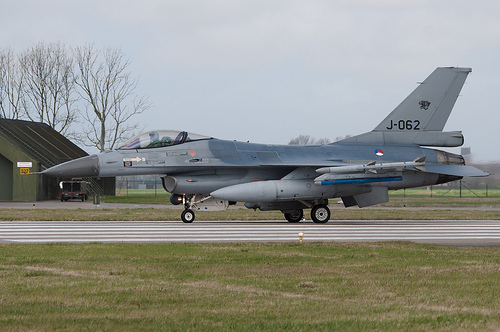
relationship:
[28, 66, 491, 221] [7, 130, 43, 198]
fighter next to building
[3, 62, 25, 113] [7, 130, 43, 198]
tree behind building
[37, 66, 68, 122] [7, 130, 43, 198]
tree behind building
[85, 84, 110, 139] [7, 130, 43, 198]
tree behind building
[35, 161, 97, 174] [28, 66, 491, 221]
nose of fighter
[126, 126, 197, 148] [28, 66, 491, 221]
cockpit of fighter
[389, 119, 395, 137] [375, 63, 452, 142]
letter on tail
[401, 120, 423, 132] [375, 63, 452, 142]
number on tail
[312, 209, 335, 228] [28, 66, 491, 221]
wheel on fighter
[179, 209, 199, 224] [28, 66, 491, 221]
wheel on fighter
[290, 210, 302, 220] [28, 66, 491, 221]
wheel on fighter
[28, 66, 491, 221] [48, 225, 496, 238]
fighter on runway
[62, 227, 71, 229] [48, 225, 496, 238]
line on runway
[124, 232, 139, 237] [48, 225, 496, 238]
line on runway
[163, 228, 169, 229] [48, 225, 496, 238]
line on runway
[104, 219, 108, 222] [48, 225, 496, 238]
line on runway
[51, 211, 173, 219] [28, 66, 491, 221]
grass around fighter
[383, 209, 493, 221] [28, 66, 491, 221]
grass around fighter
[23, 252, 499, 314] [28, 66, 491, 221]
grass around fighter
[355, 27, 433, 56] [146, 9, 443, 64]
cloud in sky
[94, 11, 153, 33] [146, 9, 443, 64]
cloud in sky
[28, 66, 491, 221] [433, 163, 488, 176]
fighter has wing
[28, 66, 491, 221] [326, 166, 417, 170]
fighter has missile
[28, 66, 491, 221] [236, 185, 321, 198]
fighter has missile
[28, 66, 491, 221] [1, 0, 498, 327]
fighter in picture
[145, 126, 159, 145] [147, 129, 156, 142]
pilot wearing helmet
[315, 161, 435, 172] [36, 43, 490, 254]
missile attached to plane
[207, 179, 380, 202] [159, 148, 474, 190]
missile under wing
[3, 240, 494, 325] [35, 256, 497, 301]
patches on ground